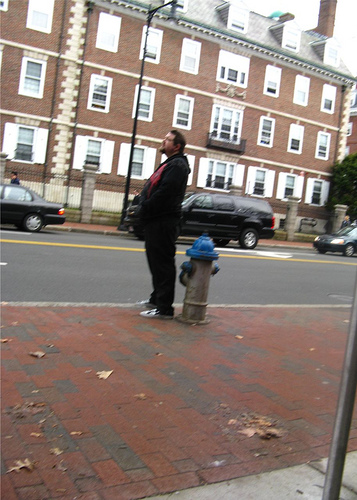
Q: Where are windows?
A: On a building.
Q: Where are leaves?
A: On the ground.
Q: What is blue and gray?
A: Fire hydrant.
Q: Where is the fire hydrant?
A: Behind man.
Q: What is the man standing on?
A: Brick walkway.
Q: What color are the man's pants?
A: Black.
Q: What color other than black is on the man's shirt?
A: Red.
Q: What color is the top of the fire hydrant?
A: Blue.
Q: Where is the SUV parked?
A: Across the street.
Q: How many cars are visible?
A: 3.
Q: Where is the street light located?
A: In front of SUV.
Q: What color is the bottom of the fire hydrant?
A: Gray.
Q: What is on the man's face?
A: Sunglasses.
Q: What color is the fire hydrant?
A: Silver and blue.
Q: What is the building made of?
A: Brick.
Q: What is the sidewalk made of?
A: Brick.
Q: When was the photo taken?
A: During the day.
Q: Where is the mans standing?
A: By a fire hydrant.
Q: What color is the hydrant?
A: Blue and gray.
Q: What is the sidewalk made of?
A: Brick.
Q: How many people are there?
A: One.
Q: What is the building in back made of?
A: Brick.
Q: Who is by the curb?
A: The man in black.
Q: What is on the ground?
A: Leaves.